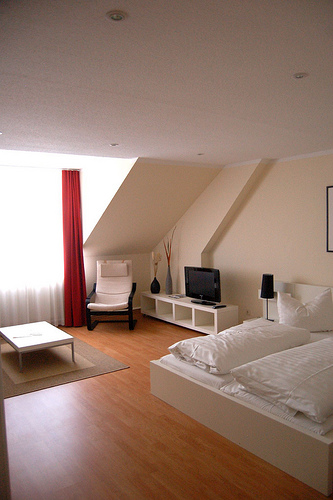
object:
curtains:
[61, 169, 88, 327]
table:
[0, 320, 75, 372]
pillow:
[276, 285, 332, 334]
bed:
[150, 278, 332, 496]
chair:
[85, 258, 139, 332]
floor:
[0, 309, 333, 499]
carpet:
[0, 320, 130, 401]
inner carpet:
[0, 340, 96, 386]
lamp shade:
[259, 273, 274, 300]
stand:
[140, 289, 239, 334]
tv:
[183, 264, 221, 306]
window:
[0, 166, 67, 294]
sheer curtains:
[0, 167, 64, 327]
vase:
[165, 265, 173, 295]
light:
[5, 385, 81, 440]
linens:
[228, 334, 333, 425]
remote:
[213, 304, 227, 309]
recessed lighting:
[108, 10, 127, 23]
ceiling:
[2, 1, 332, 162]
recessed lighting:
[295, 75, 304, 78]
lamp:
[258, 273, 274, 322]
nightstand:
[242, 314, 277, 324]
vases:
[150, 276, 160, 293]